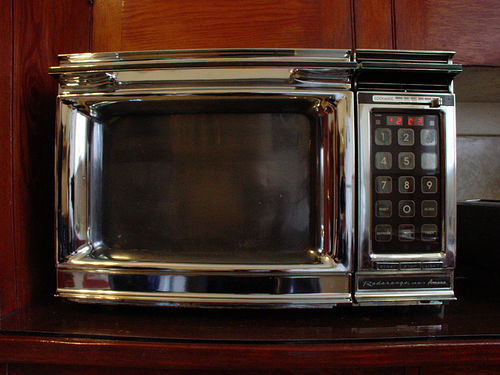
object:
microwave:
[47, 46, 465, 313]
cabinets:
[89, 0, 499, 65]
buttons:
[420, 175, 436, 193]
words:
[362, 276, 452, 286]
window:
[94, 112, 311, 250]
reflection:
[62, 107, 108, 174]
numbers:
[392, 111, 427, 130]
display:
[369, 109, 443, 130]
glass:
[7, 272, 494, 336]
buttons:
[371, 260, 401, 270]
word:
[422, 223, 440, 240]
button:
[419, 200, 440, 219]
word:
[372, 178, 390, 194]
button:
[372, 221, 391, 242]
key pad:
[376, 201, 394, 217]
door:
[57, 89, 355, 299]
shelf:
[0, 342, 488, 373]